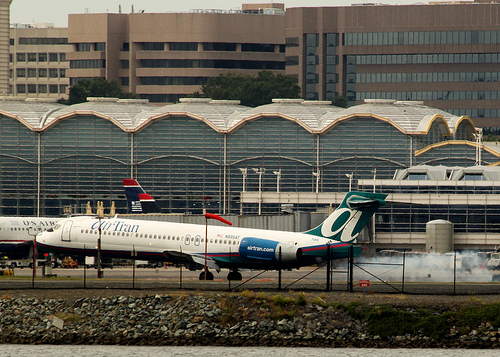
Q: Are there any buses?
A: No, there are no buses.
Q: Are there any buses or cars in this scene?
A: No, there are no buses or cars.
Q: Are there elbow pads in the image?
A: No, there are no elbow pads.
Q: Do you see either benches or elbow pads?
A: No, there are no elbow pads or benches.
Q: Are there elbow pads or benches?
A: No, there are no elbow pads or benches.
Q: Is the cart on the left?
A: Yes, the cart is on the left of the image.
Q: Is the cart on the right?
A: No, the cart is on the left of the image.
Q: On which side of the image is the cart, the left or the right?
A: The cart is on the left of the image.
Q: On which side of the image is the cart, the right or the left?
A: The cart is on the left of the image.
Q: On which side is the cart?
A: The cart is on the left of the image.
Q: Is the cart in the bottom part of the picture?
A: Yes, the cart is in the bottom of the image.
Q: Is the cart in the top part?
A: No, the cart is in the bottom of the image.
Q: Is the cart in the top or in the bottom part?
A: The cart is in the bottom of the image.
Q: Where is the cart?
A: The cart is at the plane.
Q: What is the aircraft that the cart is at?
A: The aircraft is an airplane.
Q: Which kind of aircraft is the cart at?
A: The cart is at the airplane.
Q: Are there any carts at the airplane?
A: Yes, there is a cart at the airplane.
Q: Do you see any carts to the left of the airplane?
A: Yes, there is a cart to the left of the airplane.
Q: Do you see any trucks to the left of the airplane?
A: No, there is a cart to the left of the airplane.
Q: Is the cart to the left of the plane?
A: Yes, the cart is to the left of the plane.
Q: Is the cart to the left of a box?
A: No, the cart is to the left of the plane.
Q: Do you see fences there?
A: Yes, there is a fence.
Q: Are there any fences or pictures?
A: Yes, there is a fence.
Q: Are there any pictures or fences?
A: Yes, there is a fence.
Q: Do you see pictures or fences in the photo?
A: Yes, there is a fence.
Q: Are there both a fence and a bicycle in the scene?
A: No, there is a fence but no bicycles.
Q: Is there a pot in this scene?
A: No, there are no pots.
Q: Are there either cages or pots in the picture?
A: No, there are no pots or cages.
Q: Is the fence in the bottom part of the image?
A: Yes, the fence is in the bottom of the image.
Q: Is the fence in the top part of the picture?
A: No, the fence is in the bottom of the image.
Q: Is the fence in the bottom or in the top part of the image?
A: The fence is in the bottom of the image.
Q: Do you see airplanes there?
A: Yes, there is an airplane.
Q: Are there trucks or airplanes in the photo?
A: Yes, there is an airplane.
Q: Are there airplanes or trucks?
A: Yes, there is an airplane.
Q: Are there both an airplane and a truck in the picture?
A: No, there is an airplane but no trucks.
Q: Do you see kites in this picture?
A: No, there are no kites.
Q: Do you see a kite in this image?
A: No, there are no kites.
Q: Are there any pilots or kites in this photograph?
A: No, there are no kites or pilots.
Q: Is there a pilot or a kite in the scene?
A: No, there are no kites or pilots.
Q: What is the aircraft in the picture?
A: The aircraft is an airplane.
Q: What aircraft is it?
A: The aircraft is an airplane.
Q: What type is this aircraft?
A: This is an airplane.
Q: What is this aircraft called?
A: This is an airplane.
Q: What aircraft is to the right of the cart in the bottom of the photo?
A: The aircraft is an airplane.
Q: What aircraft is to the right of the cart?
A: The aircraft is an airplane.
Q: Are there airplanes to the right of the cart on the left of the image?
A: Yes, there is an airplane to the right of the cart.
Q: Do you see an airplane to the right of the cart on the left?
A: Yes, there is an airplane to the right of the cart.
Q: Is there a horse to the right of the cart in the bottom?
A: No, there is an airplane to the right of the cart.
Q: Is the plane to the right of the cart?
A: Yes, the plane is to the right of the cart.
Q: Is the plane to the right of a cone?
A: No, the plane is to the right of the cart.